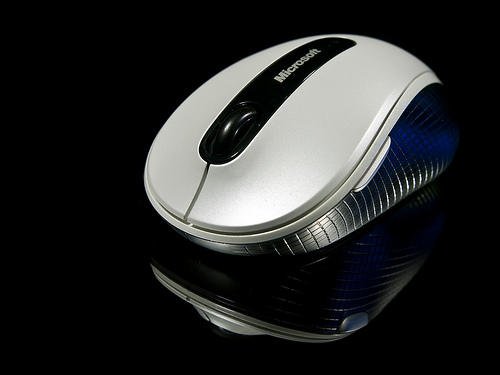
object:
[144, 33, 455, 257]
mouse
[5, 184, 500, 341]
surface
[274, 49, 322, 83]
logo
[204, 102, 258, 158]
wheel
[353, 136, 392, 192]
buttons